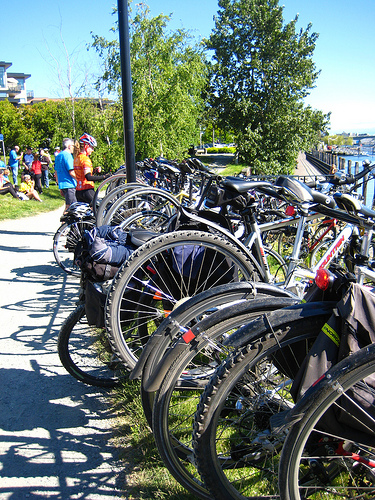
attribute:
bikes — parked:
[54, 170, 374, 491]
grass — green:
[76, 205, 371, 497]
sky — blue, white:
[3, 4, 369, 95]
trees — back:
[65, 1, 346, 168]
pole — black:
[108, 0, 148, 191]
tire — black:
[134, 300, 297, 491]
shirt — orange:
[68, 148, 101, 195]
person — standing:
[68, 130, 111, 199]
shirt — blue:
[50, 145, 78, 193]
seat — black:
[216, 173, 282, 202]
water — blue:
[331, 148, 374, 181]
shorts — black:
[60, 188, 78, 206]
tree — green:
[202, 2, 345, 184]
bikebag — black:
[261, 278, 374, 447]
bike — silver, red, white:
[103, 170, 359, 371]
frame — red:
[284, 212, 360, 285]